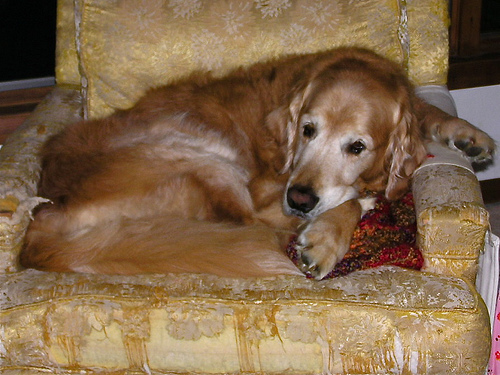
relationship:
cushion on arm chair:
[3, 264, 491, 374] [2, 2, 493, 373]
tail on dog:
[29, 205, 303, 298] [45, 45, 497, 328]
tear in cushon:
[391, 329, 419, 374] [0, 0, 494, 375]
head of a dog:
[273, 59, 384, 235] [199, 30, 498, 342]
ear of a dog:
[266, 82, 308, 170] [14, 40, 499, 283]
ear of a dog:
[377, 120, 430, 181] [104, 38, 398, 279]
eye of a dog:
[295, 100, 322, 146] [48, 49, 452, 313]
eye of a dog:
[338, 137, 368, 157] [14, 40, 499, 283]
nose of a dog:
[284, 182, 321, 214] [14, 40, 499, 283]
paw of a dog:
[286, 220, 347, 280] [14, 40, 499, 283]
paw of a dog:
[434, 111, 499, 173] [14, 40, 499, 283]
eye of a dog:
[298, 120, 317, 140] [45, 45, 497, 328]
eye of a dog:
[339, 133, 373, 157] [45, 45, 497, 328]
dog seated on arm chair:
[30, 62, 452, 278] [3, 0, 491, 374]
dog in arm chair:
[12, 44, 497, 281] [3, 0, 491, 374]